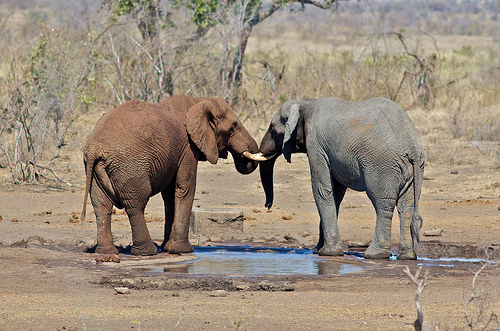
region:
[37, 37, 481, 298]
a brown and a gray member of the family Elephantidae and the order Proboscidea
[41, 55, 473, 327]
a brown and a gray elephant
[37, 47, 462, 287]
two elephants touching each other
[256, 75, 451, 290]
a gray mammal of the family Elephantidae and the order Proboscidea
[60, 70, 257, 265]
a brown mammal of the family Elephantidae and the order Proboscidea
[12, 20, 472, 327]
two mammals of the family Elephantidae and the order Proboscidea socializing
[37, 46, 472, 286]
two elephants socializing with one another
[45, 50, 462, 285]
elephants looking at each other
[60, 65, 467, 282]
the socialization of elephants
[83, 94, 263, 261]
this is an elephant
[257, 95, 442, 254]
this is an elephant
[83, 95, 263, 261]
this is a brown elephant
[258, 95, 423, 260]
this is a grey elephant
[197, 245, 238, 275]
this is a body of water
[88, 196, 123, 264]
this is an elephant's leg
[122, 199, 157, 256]
this is an elephant's leg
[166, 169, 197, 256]
this is an elephant's leg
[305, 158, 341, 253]
this is an elephant's leg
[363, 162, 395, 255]
this is an elephant's leg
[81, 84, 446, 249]
these are the elephants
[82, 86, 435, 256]
the elephants are two in umber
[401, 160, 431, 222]
this is the tail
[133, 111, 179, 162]
this is the belly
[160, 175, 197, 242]
this is the leg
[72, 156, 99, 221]
the tail is short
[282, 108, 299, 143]
this is the ear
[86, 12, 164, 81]
the tree is dry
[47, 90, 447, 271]
two elephants on the dirt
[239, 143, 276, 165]
long white tusk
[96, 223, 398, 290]
puddle of water on the ground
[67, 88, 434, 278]
brown elephant next to a gray one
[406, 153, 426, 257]
gray tail hanging down to the ground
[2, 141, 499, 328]
dirt on the ground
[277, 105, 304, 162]
ear on the side of the head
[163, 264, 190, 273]
reflection in the water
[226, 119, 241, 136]
eye on the side of the head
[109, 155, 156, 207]
lines on the skin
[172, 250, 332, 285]
water is in the puddle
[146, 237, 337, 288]
puddle is on the ground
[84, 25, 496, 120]
the trees are bare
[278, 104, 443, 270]
the elephant is gray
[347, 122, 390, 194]
dust is on the elephant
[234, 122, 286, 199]
the trunks are touching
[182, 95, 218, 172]
the ears are flared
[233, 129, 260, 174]
the trunk is curled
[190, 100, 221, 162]
ear of an elephant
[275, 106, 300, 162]
ear of an elephant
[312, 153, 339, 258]
leg of an elephant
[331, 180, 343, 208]
leg of an elephant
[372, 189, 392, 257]
leg of an elephant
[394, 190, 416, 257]
leg of an elephant